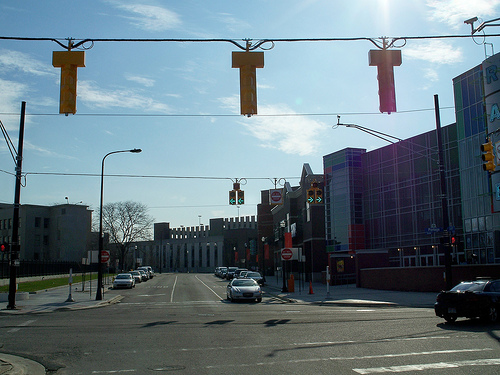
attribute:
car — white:
[213, 270, 273, 308]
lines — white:
[169, 269, 179, 311]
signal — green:
[227, 197, 244, 204]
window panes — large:
[362, 153, 444, 228]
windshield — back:
[455, 280, 485, 292]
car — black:
[435, 275, 499, 331]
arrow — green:
[228, 198, 236, 205]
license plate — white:
[446, 306, 463, 317]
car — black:
[437, 274, 499, 335]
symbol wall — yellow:
[325, 258, 360, 279]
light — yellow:
[477, 130, 496, 179]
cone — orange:
[268, 249, 326, 301]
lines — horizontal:
[193, 328, 440, 371]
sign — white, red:
[273, 244, 310, 274]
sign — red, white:
[239, 176, 344, 213]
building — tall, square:
[49, 185, 99, 263]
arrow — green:
[227, 197, 239, 209]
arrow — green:
[237, 196, 248, 207]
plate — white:
[445, 307, 460, 315]